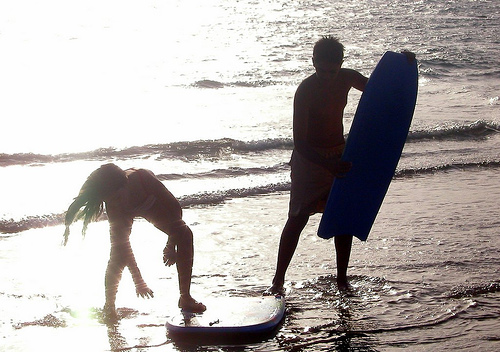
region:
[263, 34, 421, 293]
A boy holding a board.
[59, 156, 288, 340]
A girl with her foot on the board.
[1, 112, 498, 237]
Small waves crashing down near the shore.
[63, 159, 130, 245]
The girl's wet hair.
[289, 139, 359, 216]
The shorts on the boy.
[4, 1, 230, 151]
The reflection of the sun on the water.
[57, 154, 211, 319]
a woman standing on a beach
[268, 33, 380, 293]
a man standing with his surfboard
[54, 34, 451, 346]
a couple playing with boards on the beach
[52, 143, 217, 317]
a long haired girl on the shore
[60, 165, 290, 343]
a girl reaches for a boogie board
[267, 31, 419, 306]
a boy with a boogie board walks on the shoreline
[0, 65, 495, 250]
a tide crashes along the sand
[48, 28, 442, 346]
two people on a sunset beach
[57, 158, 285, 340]
a girl on the beach in the evening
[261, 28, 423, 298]
a boy with a large blue board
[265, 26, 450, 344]
Person is holding onto the boogie board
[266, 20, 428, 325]
Man's feet are in the water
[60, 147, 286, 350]
Woman flipping her hair on the beach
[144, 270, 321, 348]
Both of their feet on the board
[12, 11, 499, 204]
sun is shining on the water brightly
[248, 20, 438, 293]
Boogie board is blue in color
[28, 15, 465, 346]
Man and woman are hanging out at the beach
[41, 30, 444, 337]
Man and woman are seen as silhouettes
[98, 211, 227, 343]
Woman is reaching on the ground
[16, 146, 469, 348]
Feet is wet on their feet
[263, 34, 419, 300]
Man standing in water holding surfboard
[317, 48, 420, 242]
Blue surfboard in man's hands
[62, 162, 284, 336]
Woman bending down toward the water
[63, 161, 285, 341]
Woman with one foot on surfboard